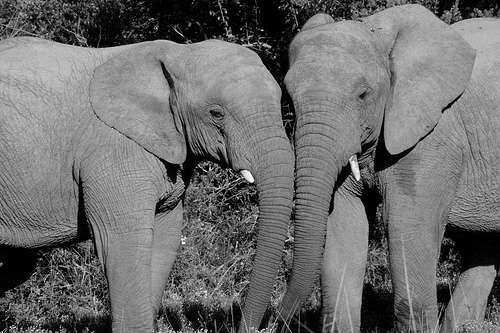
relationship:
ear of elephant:
[90, 57, 176, 157] [3, 68, 259, 316]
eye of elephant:
[201, 107, 230, 120] [3, 68, 259, 316]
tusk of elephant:
[238, 168, 261, 185] [3, 68, 259, 316]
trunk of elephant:
[237, 132, 287, 325] [3, 68, 259, 316]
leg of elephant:
[108, 243, 163, 324] [3, 68, 259, 316]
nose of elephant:
[287, 179, 315, 196] [3, 68, 259, 316]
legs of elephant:
[71, 212, 154, 317] [3, 68, 259, 316]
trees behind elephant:
[106, 2, 159, 25] [3, 68, 259, 316]